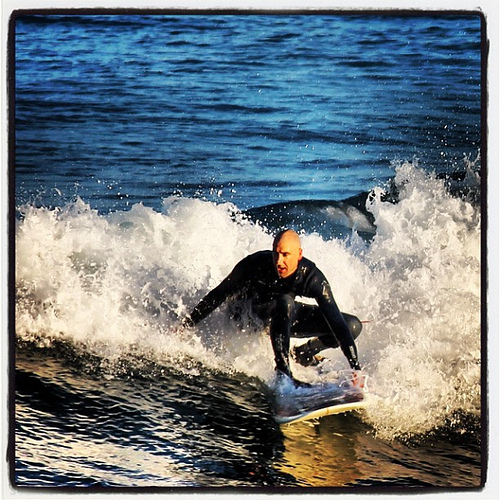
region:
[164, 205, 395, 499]
the man is surfing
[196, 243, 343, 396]
the wet suit is black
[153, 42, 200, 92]
THE WATER IS BLUE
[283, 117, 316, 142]
THE WATER IS BLUE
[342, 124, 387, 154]
THE WATER IS BLUE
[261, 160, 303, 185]
THE WATER IS BLUE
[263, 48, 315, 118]
THE WATER IS BLUE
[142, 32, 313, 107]
THE WATER IS BLUE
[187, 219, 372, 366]
THAT IS A PERSON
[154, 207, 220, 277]
THAT IS A WAVE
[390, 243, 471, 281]
THAT IS A WAVE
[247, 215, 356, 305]
the head of a man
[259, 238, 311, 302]
the face of a man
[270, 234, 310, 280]
the eyes of a man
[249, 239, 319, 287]
the nose of a man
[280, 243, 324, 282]
the ear of a man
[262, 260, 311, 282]
the mouth of a man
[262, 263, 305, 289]
the chin of a man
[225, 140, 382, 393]
a man in a wet suit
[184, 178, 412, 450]
a man on a surfboard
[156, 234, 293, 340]
the arm of a man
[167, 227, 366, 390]
the man on the water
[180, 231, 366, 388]
the man on the surf board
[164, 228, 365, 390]
the man dressed in a wet suit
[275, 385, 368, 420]
the surfboard on the water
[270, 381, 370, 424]
the surfboard under the man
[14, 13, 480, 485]
the body of water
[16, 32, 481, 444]
the water splashing around the man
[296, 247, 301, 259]
the ear on the man's head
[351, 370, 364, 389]
the man's hand holding the surfboard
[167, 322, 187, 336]
the man's hand in the water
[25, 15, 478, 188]
blue wavy water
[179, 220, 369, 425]
a man surfing in the wave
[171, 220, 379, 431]
a bald man wearing a black wet suit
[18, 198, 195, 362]
water splashing up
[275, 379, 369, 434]
the front of a surf board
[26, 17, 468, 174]
the deep blue water of the ocean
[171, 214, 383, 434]
a man is bending down on a surf board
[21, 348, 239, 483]
dark glistening water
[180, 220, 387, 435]
a man in a black wet suit is surfing through the white surf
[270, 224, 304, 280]
a bald man